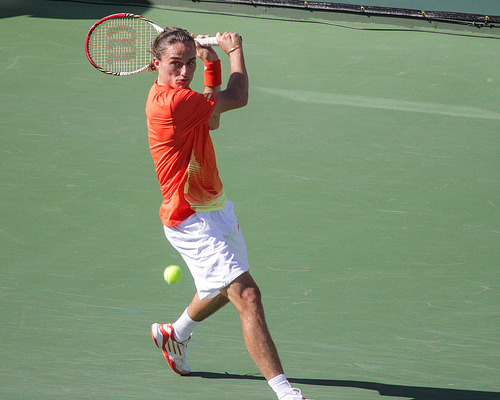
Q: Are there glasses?
A: No, there are no glasses.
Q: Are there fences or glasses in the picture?
A: No, there are no glasses or fences.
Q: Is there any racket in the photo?
A: Yes, there is a racket.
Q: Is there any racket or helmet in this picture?
A: Yes, there is a racket.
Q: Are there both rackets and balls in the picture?
A: Yes, there are both a racket and a ball.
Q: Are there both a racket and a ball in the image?
A: Yes, there are both a racket and a ball.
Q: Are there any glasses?
A: No, there are no glasses.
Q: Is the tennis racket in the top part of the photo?
A: Yes, the tennis racket is in the top of the image.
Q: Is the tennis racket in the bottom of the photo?
A: No, the tennis racket is in the top of the image.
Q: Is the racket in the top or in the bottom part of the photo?
A: The racket is in the top of the image.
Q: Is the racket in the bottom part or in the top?
A: The racket is in the top of the image.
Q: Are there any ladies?
A: No, there are no ladies.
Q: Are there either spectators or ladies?
A: No, there are no ladies or spectators.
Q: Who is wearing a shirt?
A: The man is wearing a shirt.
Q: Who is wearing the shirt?
A: The man is wearing a shirt.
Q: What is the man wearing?
A: The man is wearing a shirt.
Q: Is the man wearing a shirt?
A: Yes, the man is wearing a shirt.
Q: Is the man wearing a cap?
A: No, the man is wearing a shirt.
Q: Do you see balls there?
A: Yes, there is a ball.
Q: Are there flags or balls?
A: Yes, there is a ball.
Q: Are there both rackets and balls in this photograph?
A: Yes, there are both a ball and a racket.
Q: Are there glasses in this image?
A: No, there are no glasses.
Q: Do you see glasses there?
A: No, there are no glasses.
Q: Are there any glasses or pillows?
A: No, there are no glasses or pillows.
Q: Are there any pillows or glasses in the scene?
A: No, there are no glasses or pillows.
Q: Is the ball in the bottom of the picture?
A: Yes, the ball is in the bottom of the image.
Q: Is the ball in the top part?
A: No, the ball is in the bottom of the image.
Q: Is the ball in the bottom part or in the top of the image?
A: The ball is in the bottom of the image.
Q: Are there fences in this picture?
A: No, there are no fences.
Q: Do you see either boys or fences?
A: No, there are no fences or boys.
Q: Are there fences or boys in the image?
A: No, there are no fences or boys.